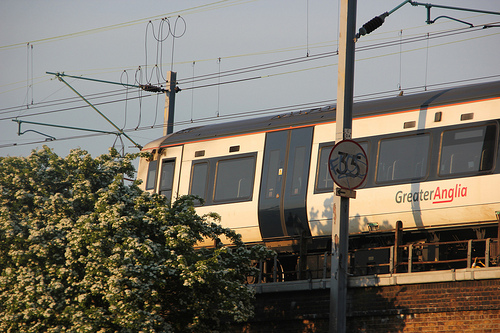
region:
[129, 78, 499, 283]
a train car traveling on the tracks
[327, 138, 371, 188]
a circular sign with the number 35 on it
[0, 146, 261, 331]
a bush in front of the brick wall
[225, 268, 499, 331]
a brick wall in front of the train tracks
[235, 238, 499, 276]
a metal railing above the brick wall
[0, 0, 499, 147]
a bunch of wire lines above the train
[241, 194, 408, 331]
the shadow of the bush on the brick wall and train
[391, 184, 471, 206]
a sign on the train that says Greater Anglia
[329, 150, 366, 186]
blue graffiti on the circular sign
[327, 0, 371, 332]
a metal pole with a circular sign on it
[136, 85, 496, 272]
a white train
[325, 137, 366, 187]
the round sign with numbers on it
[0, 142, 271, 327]
large plant on the left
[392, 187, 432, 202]
word in green on side of the train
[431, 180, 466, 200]
word in red on the side of the train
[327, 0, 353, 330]
the pole the round sign is on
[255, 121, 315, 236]
the door on the side of the train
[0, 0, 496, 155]
the clear sky above the train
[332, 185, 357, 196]
tiny sign below the round sign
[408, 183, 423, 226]
the shadow of a pole on side of the train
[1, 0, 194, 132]
the power lines for the train power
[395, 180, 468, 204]
the train route name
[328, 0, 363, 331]
a power line pole along the tracks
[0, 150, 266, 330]
a tree on the side of the tracks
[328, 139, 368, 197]
a speed limit sign on the pole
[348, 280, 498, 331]
a brown brick wall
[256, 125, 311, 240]
the trains side doors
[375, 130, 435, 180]
a trains passenger car window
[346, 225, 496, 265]
a metal safety guard rail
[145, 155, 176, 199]
the engineers side window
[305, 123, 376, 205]
round white sign with the number 35 on it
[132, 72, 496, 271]
cream and black colored electric passenger train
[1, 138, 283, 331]
large bush growing beside train tracks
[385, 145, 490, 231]
writing on side of train saying 'GreaterAnglia'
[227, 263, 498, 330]
brown brick wall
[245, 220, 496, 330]
brown metal railing along train tracks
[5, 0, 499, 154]
electrical wires above train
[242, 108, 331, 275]
tinted doorway in train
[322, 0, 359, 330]
square metal electrical pole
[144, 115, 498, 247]
tinted windows in train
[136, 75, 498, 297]
Elevated train on train tracks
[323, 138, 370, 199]
White and blue sign on pole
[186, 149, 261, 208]
Window on side of train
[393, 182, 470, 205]
Grey and red sign on side of train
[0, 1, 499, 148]
Power lines above the train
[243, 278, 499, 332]
Old worn brick bridge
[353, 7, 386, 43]
Black power coil on pole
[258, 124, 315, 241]
Glass door on side of train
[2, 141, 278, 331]
Large green tree in foreground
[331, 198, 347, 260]
Rust on grey pole